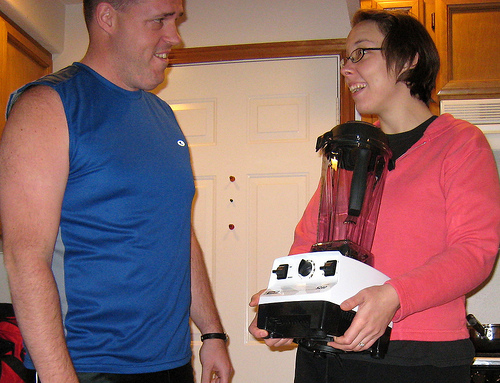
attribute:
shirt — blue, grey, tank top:
[10, 66, 196, 375]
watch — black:
[197, 330, 230, 343]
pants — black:
[21, 358, 204, 382]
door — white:
[152, 53, 342, 380]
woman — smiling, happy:
[265, 5, 497, 383]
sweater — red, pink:
[298, 115, 499, 365]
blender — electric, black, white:
[254, 120, 401, 356]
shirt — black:
[378, 110, 435, 167]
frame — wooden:
[187, 41, 346, 62]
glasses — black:
[335, 47, 382, 66]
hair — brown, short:
[360, 10, 444, 96]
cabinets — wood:
[429, 6, 499, 85]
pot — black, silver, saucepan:
[466, 310, 499, 352]